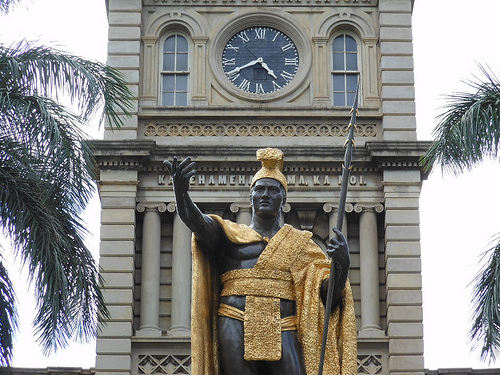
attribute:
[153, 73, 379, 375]
statue — warrior, serious, black, human, gold, kamehameha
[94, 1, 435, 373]
building — tan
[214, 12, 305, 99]
clock — roman numeral, black, large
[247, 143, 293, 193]
head band — gold, roman, broom like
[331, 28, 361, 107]
window — curved